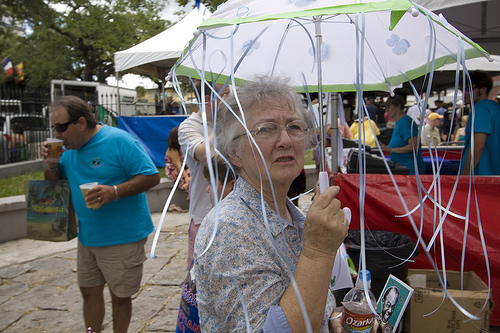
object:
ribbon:
[374, 0, 414, 40]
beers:
[79, 182, 104, 208]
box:
[404, 265, 496, 333]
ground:
[0, 211, 194, 331]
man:
[32, 97, 161, 331]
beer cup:
[45, 138, 65, 166]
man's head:
[382, 287, 399, 319]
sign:
[376, 273, 412, 333]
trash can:
[344, 225, 421, 305]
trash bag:
[345, 230, 415, 292]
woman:
[182, 82, 368, 330]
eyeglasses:
[254, 123, 311, 136]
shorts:
[68, 241, 148, 295]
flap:
[127, 254, 148, 270]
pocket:
[123, 256, 152, 280]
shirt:
[184, 172, 306, 333]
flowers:
[226, 243, 254, 277]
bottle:
[342, 267, 382, 332]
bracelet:
[111, 180, 121, 199]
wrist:
[41, 159, 62, 169]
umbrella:
[169, 0, 493, 98]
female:
[172, 79, 385, 330]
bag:
[21, 170, 74, 240]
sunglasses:
[51, 121, 72, 131]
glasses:
[51, 120, 74, 131]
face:
[46, 106, 90, 150]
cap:
[359, 270, 372, 279]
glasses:
[255, 122, 308, 137]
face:
[234, 96, 306, 179]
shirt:
[59, 140, 157, 238]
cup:
[42, 140, 65, 164]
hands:
[326, 302, 380, 333]